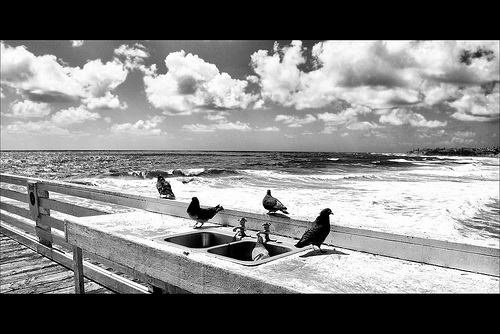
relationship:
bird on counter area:
[294, 208, 335, 252] [62, 210, 498, 293]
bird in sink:
[261, 187, 292, 216] [209, 232, 300, 275]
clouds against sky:
[0, 42, 36, 83] [83, 61, 375, 161]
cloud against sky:
[140, 48, 262, 116] [0, 38, 498, 153]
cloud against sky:
[140, 48, 262, 116] [131, 41, 272, 111]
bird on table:
[294, 208, 335, 252] [123, 209, 327, 296]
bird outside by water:
[294, 208, 335, 252] [23, 150, 108, 165]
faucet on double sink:
[225, 214, 271, 243] [145, 221, 292, 286]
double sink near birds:
[150, 213, 310, 264] [180, 168, 366, 253]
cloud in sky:
[144, 48, 256, 113] [2, 38, 499, 141]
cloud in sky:
[204, 114, 226, 123] [2, 38, 499, 141]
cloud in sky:
[346, 120, 386, 130] [2, 38, 499, 141]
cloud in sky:
[379, 109, 449, 129] [2, 38, 499, 141]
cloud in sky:
[54, 103, 103, 127] [2, 38, 499, 141]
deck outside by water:
[1, 234, 142, 305] [5, 143, 497, 307]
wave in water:
[154, 161, 236, 186] [29, 151, 74, 175]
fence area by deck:
[7, 138, 226, 295] [0, 191, 144, 307]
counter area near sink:
[79, 206, 209, 285] [167, 224, 229, 250]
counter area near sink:
[79, 206, 209, 285] [216, 235, 297, 276]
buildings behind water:
[406, 138, 497, 162] [106, 140, 337, 190]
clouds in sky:
[0, 42, 127, 120] [0, 38, 498, 153]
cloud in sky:
[140, 48, 262, 116] [0, 38, 498, 153]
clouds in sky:
[248, 38, 498, 135] [0, 38, 498, 153]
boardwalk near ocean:
[2, 173, 140, 295] [0, 149, 499, 249]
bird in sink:
[250, 235, 269, 262] [141, 210, 318, 269]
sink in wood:
[157, 228, 307, 264] [64, 207, 496, 294]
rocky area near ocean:
[412, 141, 489, 165] [0, 149, 499, 249]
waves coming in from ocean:
[262, 145, 360, 192] [0, 149, 499, 249]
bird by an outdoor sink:
[151, 172, 181, 197] [159, 222, 304, 269]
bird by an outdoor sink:
[182, 195, 223, 232] [159, 222, 304, 269]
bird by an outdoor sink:
[259, 186, 295, 216] [159, 222, 304, 269]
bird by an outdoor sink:
[296, 205, 338, 251] [159, 222, 304, 269]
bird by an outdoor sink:
[250, 235, 269, 262] [159, 222, 304, 269]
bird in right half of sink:
[250, 230, 269, 262] [205, 237, 298, 265]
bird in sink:
[294, 208, 335, 252] [160, 228, 299, 279]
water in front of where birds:
[6, 148, 498, 294] [152, 173, 335, 254]